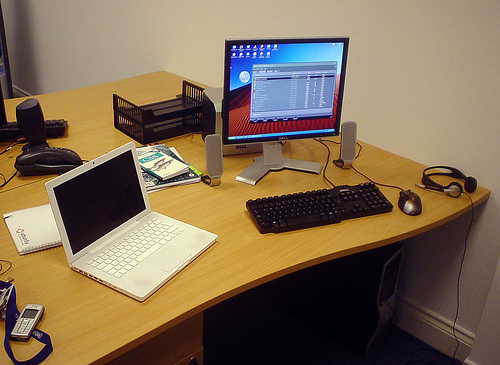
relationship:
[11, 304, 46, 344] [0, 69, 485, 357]
cell phone on desk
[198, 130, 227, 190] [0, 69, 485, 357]
speaker on desk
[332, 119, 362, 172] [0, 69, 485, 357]
speaker on desk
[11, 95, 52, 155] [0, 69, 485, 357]
speaker on desk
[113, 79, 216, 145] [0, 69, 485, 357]
holder on desk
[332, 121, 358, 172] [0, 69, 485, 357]
speaker on desk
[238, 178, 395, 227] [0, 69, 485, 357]
keyboard on desk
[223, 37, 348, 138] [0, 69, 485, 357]
monitor on desk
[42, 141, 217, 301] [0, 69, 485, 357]
laptop on desk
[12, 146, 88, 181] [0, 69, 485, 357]
phone on desk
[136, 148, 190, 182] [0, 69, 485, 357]
book on desk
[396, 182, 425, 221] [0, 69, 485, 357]
computer mouse on desk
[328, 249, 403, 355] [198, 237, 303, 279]
computer tower on desk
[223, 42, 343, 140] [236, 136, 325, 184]
monitor on base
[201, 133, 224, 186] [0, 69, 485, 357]
speaker on desk